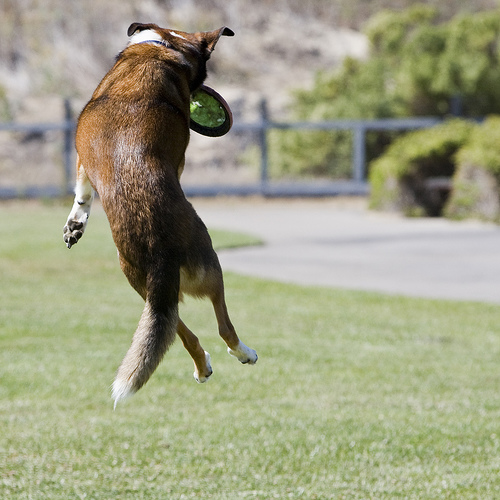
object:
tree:
[321, 81, 331, 169]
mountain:
[0, 0, 500, 193]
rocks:
[488, 203, 500, 221]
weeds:
[365, 111, 500, 227]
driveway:
[185, 196, 500, 303]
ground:
[0, 197, 500, 500]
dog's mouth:
[192, 83, 206, 95]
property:
[0, 188, 500, 499]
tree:
[493, 0, 500, 116]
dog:
[61, 21, 259, 413]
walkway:
[187, 194, 500, 304]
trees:
[393, 16, 401, 112]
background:
[0, 0, 500, 224]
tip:
[108, 378, 138, 411]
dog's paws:
[237, 348, 259, 367]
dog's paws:
[192, 362, 214, 385]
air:
[0, 0, 500, 498]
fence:
[0, 94, 445, 202]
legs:
[208, 285, 259, 366]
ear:
[200, 25, 236, 53]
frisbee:
[188, 84, 234, 138]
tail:
[109, 255, 182, 413]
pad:
[62, 219, 87, 250]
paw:
[62, 217, 82, 247]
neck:
[116, 39, 195, 67]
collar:
[137, 39, 165, 46]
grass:
[0, 198, 500, 500]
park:
[1, 0, 500, 500]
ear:
[126, 21, 150, 37]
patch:
[169, 31, 186, 40]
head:
[119, 21, 236, 95]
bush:
[476, 10, 500, 123]